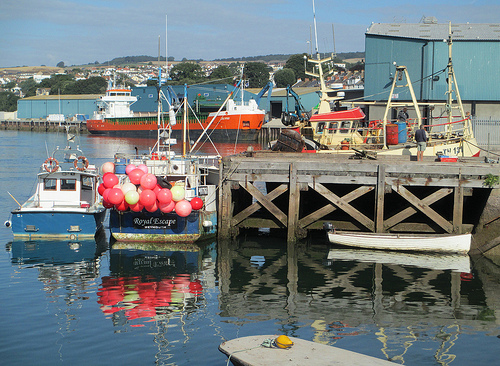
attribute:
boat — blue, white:
[5, 157, 106, 238]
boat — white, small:
[328, 227, 472, 253]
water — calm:
[0, 129, 500, 365]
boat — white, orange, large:
[86, 73, 265, 140]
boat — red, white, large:
[268, 22, 481, 161]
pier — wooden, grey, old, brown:
[219, 150, 499, 240]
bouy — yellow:
[274, 335, 294, 349]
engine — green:
[195, 95, 224, 115]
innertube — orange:
[44, 157, 61, 174]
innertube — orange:
[75, 155, 89, 172]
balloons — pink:
[98, 161, 204, 217]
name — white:
[133, 217, 178, 229]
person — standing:
[414, 124, 428, 161]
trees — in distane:
[0, 53, 366, 112]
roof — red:
[298, 106, 366, 121]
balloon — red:
[190, 197, 204, 211]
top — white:
[14, 165, 105, 211]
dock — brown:
[218, 150, 499, 249]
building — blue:
[18, 83, 262, 119]